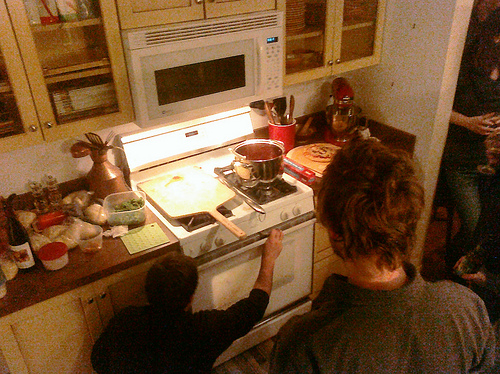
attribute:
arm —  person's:
[418, 74, 499, 150]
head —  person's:
[141, 257, 201, 313]